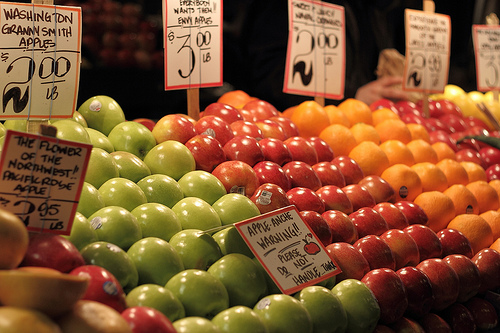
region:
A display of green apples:
[0, 95, 379, 329]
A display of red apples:
[127, 90, 498, 332]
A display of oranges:
[282, 97, 498, 251]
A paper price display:
[2, 1, 82, 118]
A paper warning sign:
[197, 201, 340, 293]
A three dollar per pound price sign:
[161, 3, 225, 93]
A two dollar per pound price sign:
[279, 1, 346, 102]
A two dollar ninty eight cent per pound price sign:
[402, 6, 450, 91]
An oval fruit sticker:
[397, 183, 407, 197]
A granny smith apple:
[125, 236, 182, 284]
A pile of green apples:
[96, 153, 203, 250]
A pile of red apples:
[245, 128, 338, 195]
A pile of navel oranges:
[383, 137, 460, 198]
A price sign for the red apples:
[161, 10, 243, 90]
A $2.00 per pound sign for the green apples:
[0, 8, 87, 120]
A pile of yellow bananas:
[449, 86, 499, 118]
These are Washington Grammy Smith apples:
[113, 165, 208, 240]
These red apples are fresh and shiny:
[217, 126, 314, 186]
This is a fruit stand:
[13, 6, 493, 323]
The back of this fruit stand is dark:
[228, 23, 283, 101]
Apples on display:
[0, 93, 497, 330]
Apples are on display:
[1, 89, 498, 331]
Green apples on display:
[0, 91, 384, 331]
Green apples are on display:
[2, 87, 391, 332]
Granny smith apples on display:
[1, 80, 387, 332]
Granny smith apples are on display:
[2, 87, 388, 330]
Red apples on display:
[143, 88, 497, 330]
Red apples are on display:
[148, 95, 498, 330]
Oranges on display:
[280, 92, 498, 277]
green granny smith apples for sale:
[22, 88, 380, 327]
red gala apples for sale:
[147, 95, 473, 309]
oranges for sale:
[281, 80, 498, 269]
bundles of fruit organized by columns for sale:
[1, 81, 497, 329]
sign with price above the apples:
[0, 1, 75, 135]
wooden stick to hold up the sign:
[183, 87, 200, 121]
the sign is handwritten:
[288, 1, 347, 101]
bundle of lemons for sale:
[431, 70, 498, 127]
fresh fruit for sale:
[0, 87, 495, 328]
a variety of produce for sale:
[0, 85, 498, 331]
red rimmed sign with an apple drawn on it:
[230, 205, 340, 291]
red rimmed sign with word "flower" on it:
[0, 125, 91, 230]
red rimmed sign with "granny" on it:
[0, 0, 80, 120]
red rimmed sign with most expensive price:
[160, 0, 221, 90]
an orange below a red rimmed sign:
[287, 100, 327, 130]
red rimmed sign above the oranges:
[280, 0, 345, 100]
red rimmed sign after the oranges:
[401, 10, 448, 95]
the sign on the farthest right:
[472, 20, 494, 85]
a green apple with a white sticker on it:
[78, 93, 120, 133]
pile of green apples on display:
[4, 89, 383, 329]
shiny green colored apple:
[174, 307, 219, 330]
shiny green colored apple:
[213, 303, 263, 330]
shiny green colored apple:
[254, 292, 314, 329]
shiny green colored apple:
[293, 280, 343, 326]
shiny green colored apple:
[336, 276, 380, 327]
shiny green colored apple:
[126, 278, 183, 320]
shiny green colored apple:
[168, 270, 230, 317]